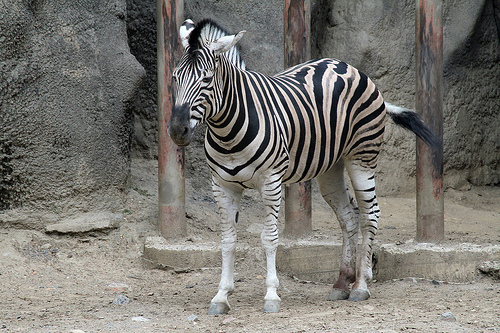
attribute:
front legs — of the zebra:
[205, 174, 283, 318]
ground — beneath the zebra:
[1, 254, 249, 331]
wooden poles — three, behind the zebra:
[154, 0, 464, 247]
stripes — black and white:
[260, 73, 349, 162]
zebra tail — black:
[384, 97, 436, 148]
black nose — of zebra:
[166, 104, 196, 150]